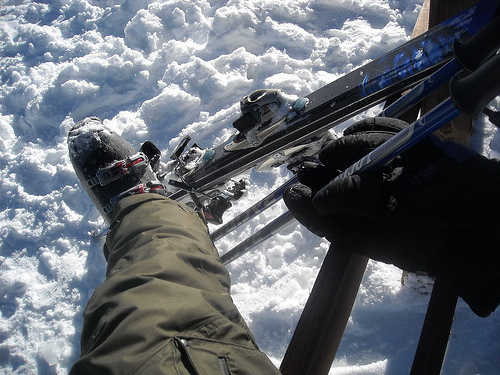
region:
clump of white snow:
[3, 260, 33, 299]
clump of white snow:
[51, 70, 117, 109]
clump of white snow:
[118, 5, 169, 49]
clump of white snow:
[201, 0, 260, 53]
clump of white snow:
[127, 70, 207, 134]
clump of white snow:
[30, 50, 102, 102]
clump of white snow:
[255, 2, 320, 57]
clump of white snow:
[326, 11, 413, 66]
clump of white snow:
[248, 212, 310, 279]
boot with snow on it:
[44, 113, 152, 211]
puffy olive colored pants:
[63, 175, 228, 357]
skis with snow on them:
[148, 55, 441, 222]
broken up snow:
[14, 68, 120, 335]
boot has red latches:
[83, 133, 187, 211]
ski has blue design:
[326, 45, 486, 102]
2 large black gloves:
[303, 119, 485, 274]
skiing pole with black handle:
[422, 36, 494, 168]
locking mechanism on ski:
[221, 91, 328, 161]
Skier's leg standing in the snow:
[61, 117, 253, 374]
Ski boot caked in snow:
[59, 122, 176, 218]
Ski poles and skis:
[150, 74, 456, 312]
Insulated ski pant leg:
[70, 189, 280, 371]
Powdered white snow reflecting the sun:
[1, 198, 82, 343]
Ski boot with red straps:
[67, 114, 163, 228]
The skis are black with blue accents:
[168, 30, 463, 207]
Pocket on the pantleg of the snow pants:
[74, 299, 291, 369]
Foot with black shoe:
[57, 113, 181, 212]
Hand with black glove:
[286, 111, 498, 310]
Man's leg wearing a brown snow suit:
[70, 193, 280, 372]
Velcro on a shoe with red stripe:
[90, 146, 149, 188]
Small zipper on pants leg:
[217, 351, 235, 370]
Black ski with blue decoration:
[158, 6, 493, 200]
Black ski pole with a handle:
[213, 53, 493, 269]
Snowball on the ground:
[133, 83, 201, 140]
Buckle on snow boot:
[81, 173, 104, 190]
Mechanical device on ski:
[163, 135, 214, 171]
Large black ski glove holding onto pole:
[286, 116, 498, 317]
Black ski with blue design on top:
[165, 5, 492, 195]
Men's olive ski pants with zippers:
[67, 192, 278, 374]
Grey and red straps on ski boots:
[83, 150, 167, 193]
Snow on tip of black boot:
[67, 120, 112, 156]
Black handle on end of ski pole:
[449, 45, 498, 120]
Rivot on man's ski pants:
[179, 338, 187, 345]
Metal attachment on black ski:
[221, 89, 298, 151]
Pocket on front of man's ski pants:
[168, 338, 283, 374]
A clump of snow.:
[106, 110, 140, 139]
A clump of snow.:
[141, 82, 210, 119]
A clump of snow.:
[213, 70, 263, 102]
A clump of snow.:
[252, 40, 287, 67]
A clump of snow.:
[263, 15, 328, 56]